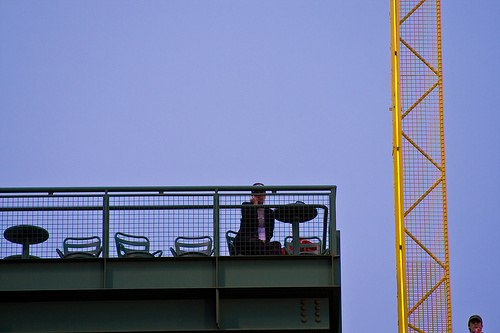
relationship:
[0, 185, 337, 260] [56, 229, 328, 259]
fence in front of seats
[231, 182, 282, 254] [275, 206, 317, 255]
person near table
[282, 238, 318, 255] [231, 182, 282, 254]
red object near person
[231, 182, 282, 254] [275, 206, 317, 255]
person at table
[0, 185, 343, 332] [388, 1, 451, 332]
deck near tower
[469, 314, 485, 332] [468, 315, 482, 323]
man wearing a cap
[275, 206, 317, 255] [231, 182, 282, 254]
table near person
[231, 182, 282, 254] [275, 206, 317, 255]
person sitting at table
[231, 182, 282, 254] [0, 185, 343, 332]
person on deck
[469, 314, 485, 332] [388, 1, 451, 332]
man near tower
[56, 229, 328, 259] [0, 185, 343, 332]
seats on deck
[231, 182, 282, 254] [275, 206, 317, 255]
person next to table